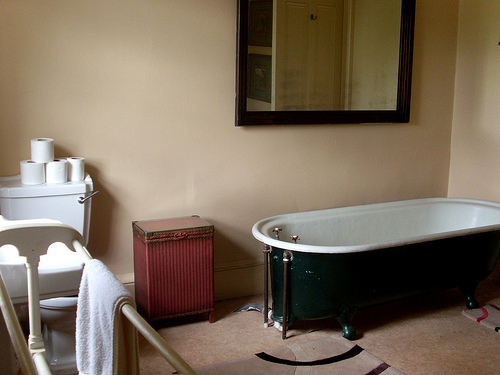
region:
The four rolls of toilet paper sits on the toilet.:
[1, 136, 114, 200]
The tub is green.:
[247, 191, 484, 332]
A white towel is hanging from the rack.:
[66, 256, 162, 371]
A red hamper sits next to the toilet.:
[131, 207, 244, 338]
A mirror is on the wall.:
[193, 7, 430, 152]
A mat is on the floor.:
[225, 322, 410, 370]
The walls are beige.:
[46, 29, 468, 208]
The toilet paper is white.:
[16, 136, 101, 228]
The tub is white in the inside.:
[261, 206, 491, 322]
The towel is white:
[55, 247, 174, 361]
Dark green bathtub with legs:
[248, 204, 499, 319]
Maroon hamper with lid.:
[132, 217, 224, 327]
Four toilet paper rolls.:
[21, 135, 86, 185]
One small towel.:
[456, 293, 498, 345]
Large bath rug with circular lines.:
[183, 331, 398, 373]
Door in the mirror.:
[271, 0, 351, 110]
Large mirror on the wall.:
[220, 1, 415, 139]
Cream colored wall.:
[0, 0, 492, 269]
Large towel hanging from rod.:
[60, 252, 138, 373]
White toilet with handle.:
[1, 175, 127, 358]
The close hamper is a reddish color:
[121, 212, 251, 336]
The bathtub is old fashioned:
[246, 185, 496, 352]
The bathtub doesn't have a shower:
[234, 201, 496, 349]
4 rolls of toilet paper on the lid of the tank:
[4, 128, 95, 194]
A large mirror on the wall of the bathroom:
[224, 8, 440, 139]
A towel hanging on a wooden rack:
[30, 246, 150, 374]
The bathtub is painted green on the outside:
[255, 191, 498, 322]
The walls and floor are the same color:
[199, 133, 278, 360]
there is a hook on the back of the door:
[304, 6, 321, 31]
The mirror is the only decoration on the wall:
[24, 6, 477, 169]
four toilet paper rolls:
[16, 134, 92, 184]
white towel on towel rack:
[3, 219, 192, 368]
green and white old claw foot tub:
[248, 192, 498, 340]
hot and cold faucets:
[268, 224, 305, 244]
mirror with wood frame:
[233, 2, 422, 128]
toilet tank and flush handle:
[1, 175, 96, 249]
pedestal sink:
[0, 210, 97, 309]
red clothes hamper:
[133, 212, 227, 323]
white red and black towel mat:
[464, 292, 499, 343]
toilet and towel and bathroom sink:
[3, 123, 161, 345]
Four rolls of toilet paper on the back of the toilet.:
[21, 131, 86, 189]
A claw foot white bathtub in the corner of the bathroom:
[254, 204, 498, 343]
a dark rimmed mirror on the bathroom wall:
[226, 1, 423, 133]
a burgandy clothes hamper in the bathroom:
[129, 213, 231, 330]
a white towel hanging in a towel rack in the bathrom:
[80, 249, 140, 374]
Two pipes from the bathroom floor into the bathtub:
[258, 238, 299, 348]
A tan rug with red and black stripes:
[456, 288, 497, 349]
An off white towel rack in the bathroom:
[1, 203, 168, 373]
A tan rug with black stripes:
[219, 338, 430, 373]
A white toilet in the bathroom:
[0, 114, 123, 367]